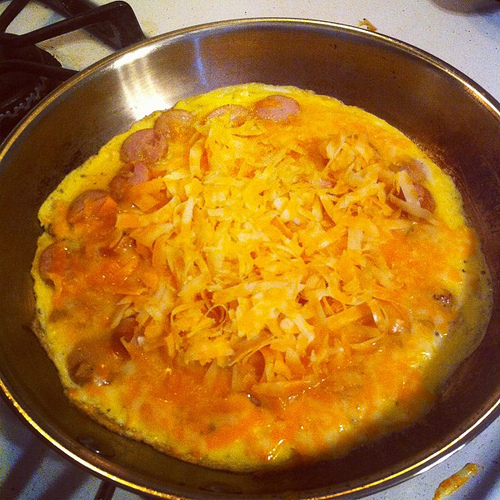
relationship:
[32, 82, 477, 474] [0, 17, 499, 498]
omelet on pan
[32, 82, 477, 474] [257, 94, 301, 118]
omelet has sausage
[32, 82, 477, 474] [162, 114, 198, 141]
omelet has sausage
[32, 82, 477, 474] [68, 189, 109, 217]
omelet has sausage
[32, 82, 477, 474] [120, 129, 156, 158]
omelet has sausage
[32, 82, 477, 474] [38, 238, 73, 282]
omelet has sausage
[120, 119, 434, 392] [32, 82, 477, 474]
cheese on omelet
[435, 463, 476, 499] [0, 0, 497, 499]
omelet part on stove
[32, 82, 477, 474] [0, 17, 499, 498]
omelet in pan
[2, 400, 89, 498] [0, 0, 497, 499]
shadow on stove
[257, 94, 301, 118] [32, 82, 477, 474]
sausage in omelet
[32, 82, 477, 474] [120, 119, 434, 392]
omelet has cheese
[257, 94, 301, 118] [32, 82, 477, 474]
sausage on omelet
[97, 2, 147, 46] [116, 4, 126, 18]
edge has part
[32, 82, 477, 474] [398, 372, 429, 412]
omelet has yolk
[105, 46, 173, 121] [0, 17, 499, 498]
highlight on pan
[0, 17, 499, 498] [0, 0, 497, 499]
pan on stove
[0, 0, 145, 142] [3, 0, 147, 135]
burner has support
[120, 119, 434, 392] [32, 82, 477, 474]
cheese over omelet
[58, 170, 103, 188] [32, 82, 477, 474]
bubbles on omelet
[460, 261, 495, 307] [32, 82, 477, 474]
bubbles on omelet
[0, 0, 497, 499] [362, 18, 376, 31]
stove has stain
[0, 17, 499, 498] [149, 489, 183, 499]
pan has residue